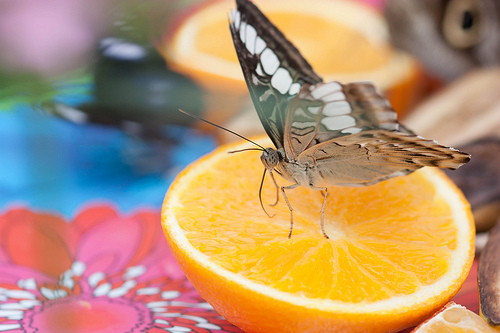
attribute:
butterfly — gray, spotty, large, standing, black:
[207, 2, 472, 231]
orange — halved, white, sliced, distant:
[166, 137, 480, 332]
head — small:
[255, 145, 282, 174]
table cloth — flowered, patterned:
[6, 88, 195, 331]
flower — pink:
[3, 198, 194, 330]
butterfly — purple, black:
[47, 33, 207, 150]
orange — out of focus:
[169, 5, 423, 119]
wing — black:
[224, 5, 322, 111]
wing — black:
[290, 85, 466, 187]